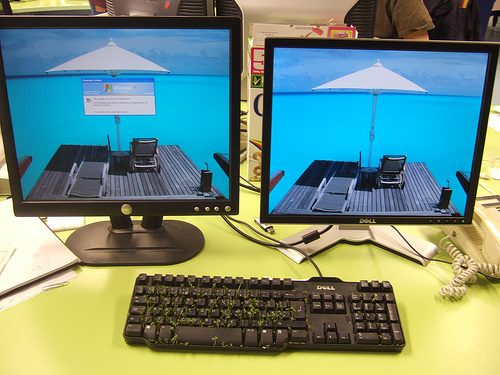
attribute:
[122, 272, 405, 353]
keyboard — black